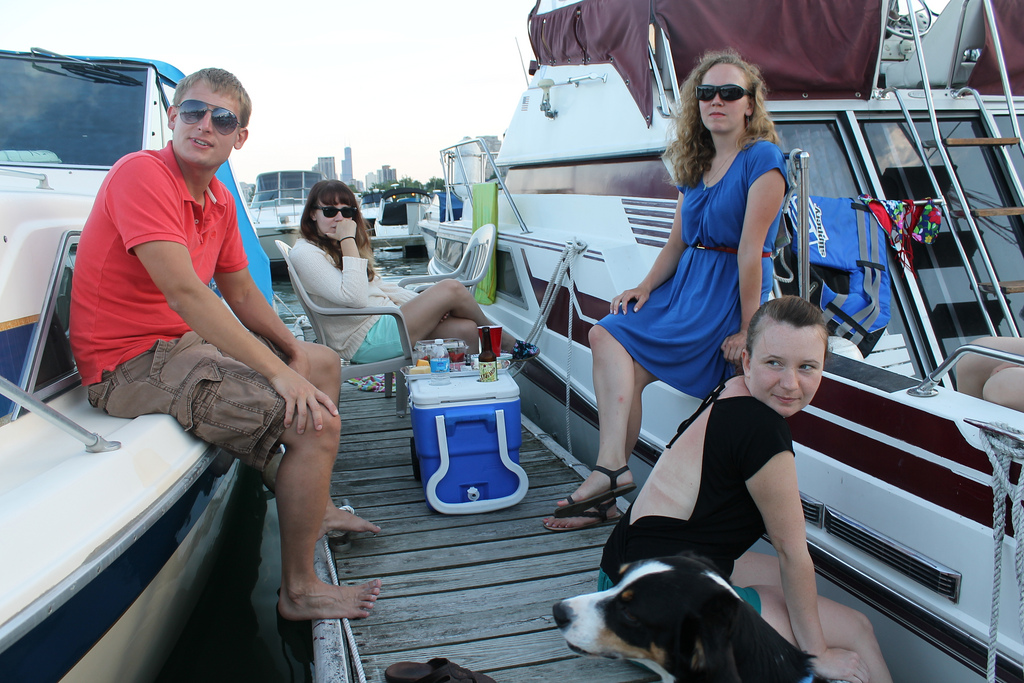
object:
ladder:
[906, 1, 1024, 343]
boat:
[269, 0, 1020, 682]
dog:
[545, 555, 829, 680]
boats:
[243, 141, 441, 263]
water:
[273, 264, 427, 319]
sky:
[0, 0, 520, 180]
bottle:
[429, 337, 453, 385]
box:
[405, 352, 529, 517]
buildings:
[310, 143, 405, 191]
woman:
[529, 51, 791, 535]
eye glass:
[692, 84, 757, 101]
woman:
[288, 179, 537, 364]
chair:
[269, 227, 414, 417]